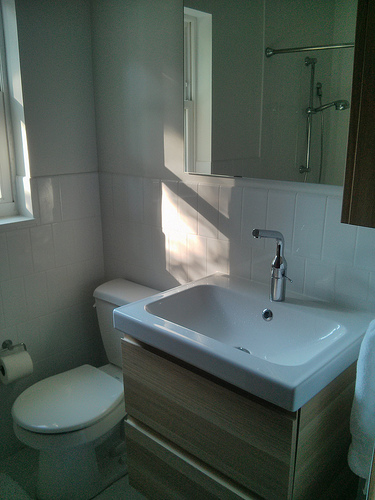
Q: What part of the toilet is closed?
A: The lid.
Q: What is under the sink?
A: A cabinet with drawers.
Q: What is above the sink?
A: A mirror on the wall.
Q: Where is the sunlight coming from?
A: The window.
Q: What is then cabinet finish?
A: Pine.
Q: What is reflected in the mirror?
A: The shower.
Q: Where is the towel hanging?
A: Beside the sink.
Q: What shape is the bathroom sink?
A: Rectangle.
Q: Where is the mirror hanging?
A: On the wall.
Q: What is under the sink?
A: Wooden drawers.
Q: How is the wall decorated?
A: With white tiles.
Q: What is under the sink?
A: Two drawers.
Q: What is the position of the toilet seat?
A: Down.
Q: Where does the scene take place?
A: In a bathroom.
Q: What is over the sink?
A: A faucet.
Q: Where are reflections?
A: In the mirror.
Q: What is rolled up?
A: Toilet paper.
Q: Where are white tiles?
A: On the walls.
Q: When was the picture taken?
A: During the daytime.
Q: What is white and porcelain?
A: The sink.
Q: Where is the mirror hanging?
A: On the wall.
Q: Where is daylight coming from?
A: A window.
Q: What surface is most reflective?
A: The mirror.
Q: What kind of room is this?
A: A bathroom.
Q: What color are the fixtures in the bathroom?
A: White.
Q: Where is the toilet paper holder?
A: On the wall.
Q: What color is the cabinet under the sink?
A: Brown.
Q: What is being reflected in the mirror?
A: The shower.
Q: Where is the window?
A: Above the toilet paper holder.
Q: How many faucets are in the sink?
A: 1.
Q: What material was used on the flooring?
A: Tiles.